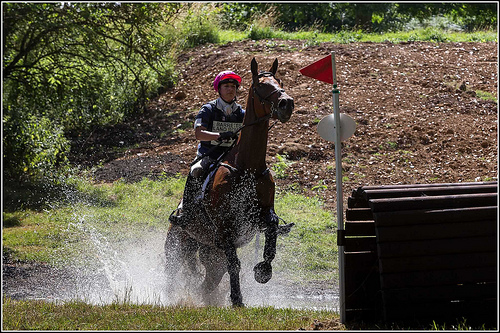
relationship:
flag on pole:
[299, 54, 332, 86] [331, 50, 345, 326]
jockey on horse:
[178, 67, 243, 234] [162, 56, 297, 307]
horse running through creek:
[162, 56, 297, 307] [5, 262, 342, 312]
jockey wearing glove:
[178, 67, 243, 234] [216, 129, 241, 143]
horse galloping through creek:
[162, 56, 297, 307] [5, 262, 342, 312]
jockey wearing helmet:
[178, 67, 243, 234] [212, 69, 242, 93]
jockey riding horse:
[178, 67, 243, 234] [162, 56, 297, 307]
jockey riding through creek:
[178, 67, 243, 234] [5, 262, 342, 312]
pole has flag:
[331, 50, 345, 326] [299, 54, 332, 86]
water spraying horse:
[24, 117, 274, 307] [162, 56, 297, 307]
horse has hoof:
[162, 56, 297, 307] [251, 260, 276, 285]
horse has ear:
[162, 56, 297, 307] [247, 56, 261, 80]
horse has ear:
[162, 56, 297, 307] [269, 54, 280, 74]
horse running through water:
[162, 56, 297, 307] [24, 117, 274, 307]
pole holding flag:
[331, 50, 345, 326] [299, 54, 332, 86]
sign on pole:
[316, 113, 358, 148] [331, 50, 345, 326]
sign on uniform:
[208, 120, 243, 147] [191, 97, 245, 162]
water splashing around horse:
[24, 117, 274, 307] [162, 56, 297, 307]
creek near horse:
[5, 262, 342, 312] [162, 56, 297, 307]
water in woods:
[0, 276, 342, 305] [4, 4, 221, 204]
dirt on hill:
[78, 34, 497, 218] [49, 28, 482, 182]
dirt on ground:
[78, 34, 497, 218] [0, 39, 484, 324]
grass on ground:
[2, 297, 339, 329] [8, 28, 484, 308]